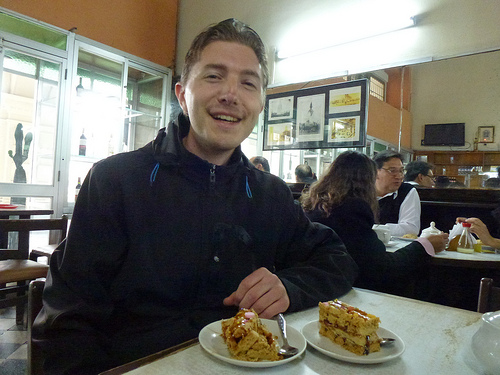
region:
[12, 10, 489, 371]
A person is sitting at a table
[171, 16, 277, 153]
The person has a smile on his face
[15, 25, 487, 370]
The people are sitting in a diner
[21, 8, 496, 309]
The people are enjoying their meal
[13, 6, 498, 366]
The people are getting some food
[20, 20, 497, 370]
The people are on their lunch break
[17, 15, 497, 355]
The people are having a good time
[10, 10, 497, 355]
The people are getting along well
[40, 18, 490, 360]
The people are out in the daytime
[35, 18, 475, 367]
The people are enjoying their day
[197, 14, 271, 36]
Person has light brown hair.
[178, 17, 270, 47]
Person has short hair.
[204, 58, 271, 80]
Person has brown eye brows.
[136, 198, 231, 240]
Person wearing black jacket.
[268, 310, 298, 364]
Silver spoon on oval plate.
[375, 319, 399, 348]
Silver spoon on oval plate.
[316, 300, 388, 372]
White oval plate sitting table.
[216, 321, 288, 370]
White oval plate sitting on table.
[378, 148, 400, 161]
Man has dark hair.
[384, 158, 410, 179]
Glasses on man's head.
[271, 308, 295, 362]
a spoon the plate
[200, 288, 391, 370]
two plates of food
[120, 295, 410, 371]
the table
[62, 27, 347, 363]
a man sitting at a table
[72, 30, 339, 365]
a man in a blue jacket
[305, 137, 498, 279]
people sitting at a table behind the man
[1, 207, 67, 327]
a chair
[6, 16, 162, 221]
the glass door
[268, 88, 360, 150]
a picture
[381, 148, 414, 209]
a person wearing glasses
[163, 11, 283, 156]
head of a person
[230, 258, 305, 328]
hand of a person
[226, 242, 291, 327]
fingers of a person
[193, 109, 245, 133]
smile of a person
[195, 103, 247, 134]
mouth of a person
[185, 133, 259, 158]
jaw of a person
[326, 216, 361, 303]
elbow of a person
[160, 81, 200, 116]
ear of a person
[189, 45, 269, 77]
forehead of a person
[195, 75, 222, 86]
eye of a person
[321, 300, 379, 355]
food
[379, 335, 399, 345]
a spoon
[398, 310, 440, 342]
a table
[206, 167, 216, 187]
a zipper on the jacket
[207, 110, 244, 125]
man is smiling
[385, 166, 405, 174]
man wearing eye glasses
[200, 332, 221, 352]
the plate is white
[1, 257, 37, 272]
a chair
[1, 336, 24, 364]
the floor is black and white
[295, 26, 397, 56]
sunlight on the wall